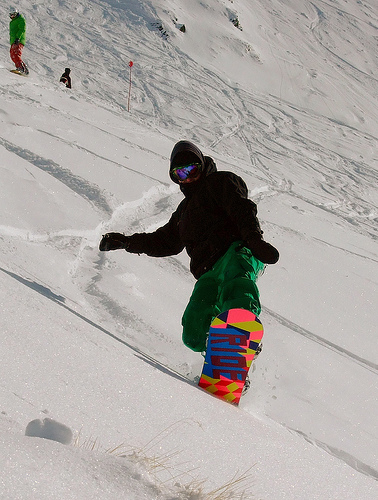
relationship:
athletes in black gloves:
[133, 146, 266, 310] [97, 228, 136, 255]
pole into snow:
[115, 54, 144, 110] [1, 1, 373, 367]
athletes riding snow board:
[133, 146, 266, 310] [186, 302, 266, 414]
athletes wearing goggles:
[133, 146, 266, 310] [158, 156, 197, 201]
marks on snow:
[39, 50, 345, 210] [2, 1, 376, 497]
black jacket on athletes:
[128, 182, 264, 271] [133, 146, 266, 310]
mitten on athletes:
[254, 240, 279, 264] [133, 146, 266, 310]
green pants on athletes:
[181, 239, 267, 351] [133, 146, 266, 310]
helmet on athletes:
[6, 5, 17, 15] [2, 1, 30, 88]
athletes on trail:
[133, 146, 266, 310] [58, 183, 185, 377]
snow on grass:
[2, 1, 376, 497] [81, 414, 266, 498]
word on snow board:
[209, 331, 247, 381] [195, 306, 261, 422]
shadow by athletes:
[1, 269, 199, 384] [133, 146, 266, 310]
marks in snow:
[39, 50, 346, 206] [0, 3, 363, 222]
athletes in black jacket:
[133, 146, 266, 310] [128, 182, 264, 271]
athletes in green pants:
[133, 146, 266, 310] [181, 239, 267, 351]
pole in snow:
[115, 54, 144, 110] [2, 1, 376, 497]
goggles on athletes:
[170, 162, 204, 181] [133, 146, 266, 310]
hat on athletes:
[167, 137, 205, 175] [133, 146, 266, 310]